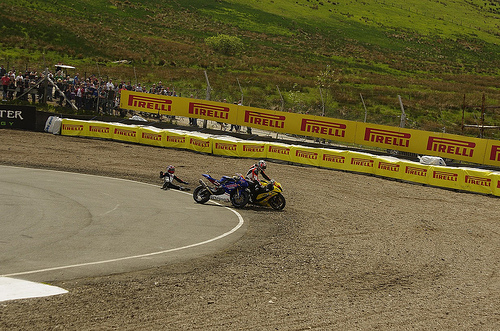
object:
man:
[245, 160, 271, 200]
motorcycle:
[232, 177, 285, 210]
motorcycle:
[193, 172, 248, 208]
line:
[1, 162, 243, 279]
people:
[0, 65, 176, 120]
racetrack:
[0, 160, 249, 286]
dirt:
[0, 129, 499, 327]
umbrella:
[53, 63, 75, 68]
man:
[159, 165, 190, 191]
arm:
[174, 175, 184, 183]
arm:
[160, 174, 165, 178]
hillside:
[1, 0, 500, 71]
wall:
[0, 102, 499, 200]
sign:
[63, 94, 500, 189]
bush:
[205, 28, 246, 55]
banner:
[61, 90, 500, 197]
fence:
[0, 55, 500, 165]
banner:
[0, 102, 38, 130]